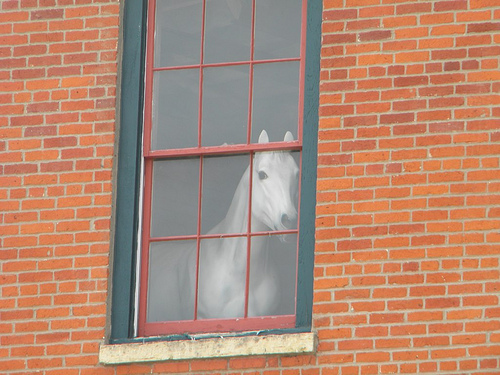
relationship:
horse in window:
[170, 124, 300, 320] [93, 2, 325, 369]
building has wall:
[4, 1, 499, 372] [2, 1, 496, 373]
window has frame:
[93, 2, 325, 369] [106, 0, 326, 349]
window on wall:
[93, 2, 325, 369] [2, 1, 496, 373]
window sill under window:
[95, 329, 323, 369] [93, 2, 325, 369]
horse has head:
[170, 124, 300, 320] [235, 125, 300, 253]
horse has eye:
[170, 124, 300, 320] [252, 164, 274, 188]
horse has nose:
[170, 124, 300, 320] [278, 207, 297, 232]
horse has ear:
[170, 124, 300, 320] [254, 125, 275, 149]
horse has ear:
[170, 124, 300, 320] [279, 129, 299, 150]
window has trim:
[93, 2, 325, 369] [133, 1, 308, 335]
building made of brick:
[4, 1, 499, 372] [345, 66, 374, 81]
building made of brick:
[4, 1, 499, 372] [379, 85, 423, 104]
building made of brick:
[4, 1, 499, 372] [339, 135, 379, 156]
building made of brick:
[4, 1, 499, 372] [21, 120, 61, 141]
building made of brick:
[4, 1, 499, 372] [38, 157, 77, 177]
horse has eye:
[170, 124, 300, 320] [289, 166, 301, 184]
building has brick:
[4, 1, 499, 372] [345, 66, 374, 81]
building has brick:
[4, 1, 499, 372] [379, 85, 423, 104]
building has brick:
[4, 1, 499, 372] [339, 135, 379, 156]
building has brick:
[4, 1, 499, 372] [38, 157, 77, 177]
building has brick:
[4, 1, 499, 372] [21, 120, 61, 141]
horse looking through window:
[170, 124, 300, 320] [93, 2, 325, 369]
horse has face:
[170, 124, 300, 320] [247, 158, 298, 247]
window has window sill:
[93, 2, 325, 369] [95, 329, 323, 369]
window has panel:
[93, 2, 325, 369] [204, 66, 251, 146]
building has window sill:
[4, 1, 499, 372] [95, 329, 323, 369]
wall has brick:
[2, 1, 496, 373] [345, 66, 374, 81]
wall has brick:
[2, 1, 496, 373] [379, 85, 423, 104]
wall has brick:
[2, 1, 496, 373] [339, 135, 379, 156]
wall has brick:
[2, 1, 496, 373] [21, 120, 61, 141]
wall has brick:
[2, 1, 496, 373] [38, 157, 77, 177]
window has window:
[93, 2, 325, 369] [93, 2, 325, 369]